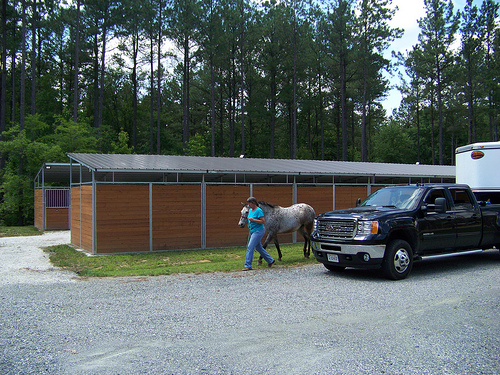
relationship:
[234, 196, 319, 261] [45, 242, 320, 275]
horse on grass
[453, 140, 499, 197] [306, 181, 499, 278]
trailer attached to truck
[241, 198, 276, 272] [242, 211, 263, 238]
man wearing shirt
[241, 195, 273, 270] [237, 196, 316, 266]
man walking horse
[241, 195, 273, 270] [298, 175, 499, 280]
man by truck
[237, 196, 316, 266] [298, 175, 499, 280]
horse by truck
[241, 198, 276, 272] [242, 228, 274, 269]
man wearing blue jeans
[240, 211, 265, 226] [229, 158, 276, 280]
shirt on woman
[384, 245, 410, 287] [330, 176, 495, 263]
tire on truck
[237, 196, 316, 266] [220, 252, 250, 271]
horse on grass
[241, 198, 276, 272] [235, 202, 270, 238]
man wearing shirt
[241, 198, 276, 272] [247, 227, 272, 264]
man wearing jeans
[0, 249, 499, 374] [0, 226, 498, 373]
gravel on road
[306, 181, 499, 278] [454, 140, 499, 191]
truck pulling trailer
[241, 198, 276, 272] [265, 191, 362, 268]
man leading horse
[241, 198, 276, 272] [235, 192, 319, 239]
man with horse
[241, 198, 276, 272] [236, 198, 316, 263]
man with horse